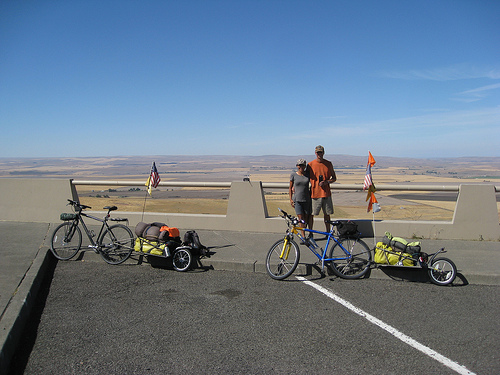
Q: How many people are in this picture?
A: Two.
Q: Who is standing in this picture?
A: A man and woman.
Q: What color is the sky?
A: Blue.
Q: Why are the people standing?
A: They are posing for a picture.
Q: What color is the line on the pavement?
A: White.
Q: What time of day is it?
A: Daytime.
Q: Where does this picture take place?
A: On a bridge.